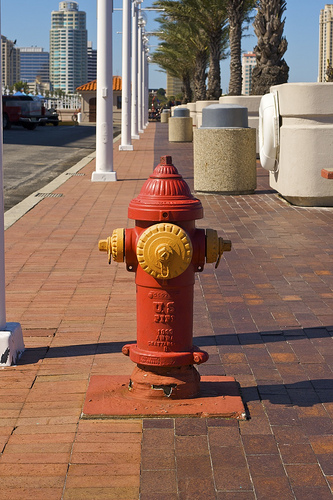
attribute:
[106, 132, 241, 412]
hydrant — red, yellow, close, metal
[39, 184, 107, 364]
sidewalk — brick, red, close, yellow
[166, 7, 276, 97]
tree — green, calm, palm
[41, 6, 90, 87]
building — far, white, tall, wide, long, high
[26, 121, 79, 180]
road — paved, black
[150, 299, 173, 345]
text — raised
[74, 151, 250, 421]
fire hydrant — red